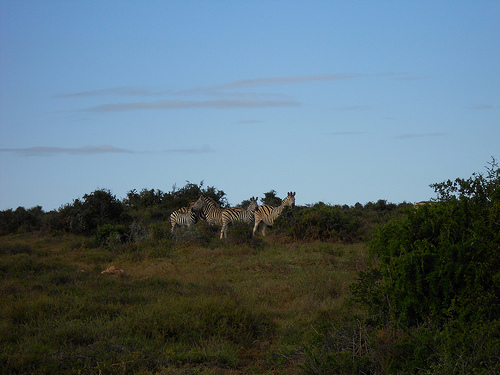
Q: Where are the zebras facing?
A: Towards the horizon.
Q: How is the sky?
A: Clear and blue.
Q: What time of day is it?
A: Evening hours.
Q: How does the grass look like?
A: Green and thick.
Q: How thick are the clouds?
A: The clouds are wispy.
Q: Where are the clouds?
A: The clouds are in the sky.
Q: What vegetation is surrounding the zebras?
A: Tall grass.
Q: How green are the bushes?
A: The bushes are green and lush.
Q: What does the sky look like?
A: The sky is blue with few clouds.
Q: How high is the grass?
A: The grass is medium height.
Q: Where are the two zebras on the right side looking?
A: Zebras are looking at the camera.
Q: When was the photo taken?
A: In the daytime.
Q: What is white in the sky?
A: Clouds.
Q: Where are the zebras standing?
A: On grass.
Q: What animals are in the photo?
A: Zebras.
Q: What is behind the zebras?
A: Bushes.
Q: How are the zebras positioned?
A: Standing.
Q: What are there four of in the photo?
A: Zebras.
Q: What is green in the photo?
A: Grass and bushes.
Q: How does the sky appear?
A: Cloudy.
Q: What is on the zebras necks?
A: Manes.